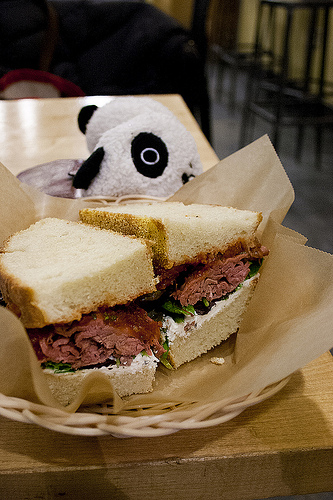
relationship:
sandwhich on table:
[12, 220, 261, 382] [15, 100, 44, 129]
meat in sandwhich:
[178, 252, 255, 320] [12, 220, 261, 382]